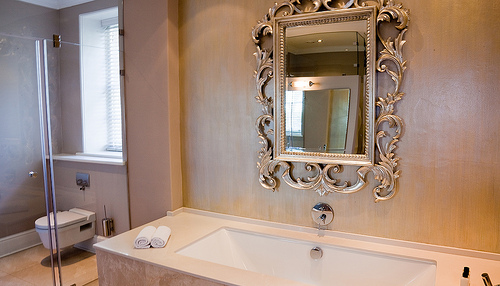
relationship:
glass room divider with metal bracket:
[236, 81, 381, 140] [52, 32, 62, 47]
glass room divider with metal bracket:
[236, 81, 381, 140] [118, 67, 127, 78]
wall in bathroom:
[0, 0, 60, 238] [1, 0, 498, 283]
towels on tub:
[133, 222, 171, 249] [206, 236, 427, 275]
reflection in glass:
[292, 50, 355, 156] [280, 19, 363, 155]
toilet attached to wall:
[34, 203, 94, 248] [47, 158, 126, 233]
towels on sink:
[150, 222, 171, 249] [81, 202, 498, 284]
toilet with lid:
[34, 203, 94, 248] [31, 207, 87, 230]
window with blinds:
[78, 9, 128, 159] [103, 29, 123, 154]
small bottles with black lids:
[455, 257, 487, 282] [452, 257, 490, 282]